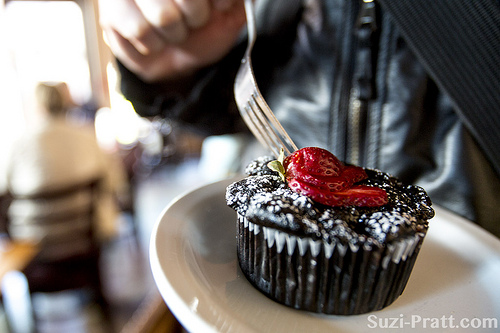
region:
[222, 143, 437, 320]
this is a cupcake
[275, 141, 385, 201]
this is a strawberry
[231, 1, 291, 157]
this is a fork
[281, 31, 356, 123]
this is a black in colour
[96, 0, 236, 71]
this is a hand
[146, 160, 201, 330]
this is the edge of a plate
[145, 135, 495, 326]
this is a white plate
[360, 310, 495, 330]
this is a word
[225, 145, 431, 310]
this is a black cupcake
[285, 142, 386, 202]
this is red in colour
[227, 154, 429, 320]
the cake is on the sauce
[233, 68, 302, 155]
the folk is metallic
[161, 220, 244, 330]
the plate is white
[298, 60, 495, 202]
the jacket is black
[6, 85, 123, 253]
the man is on the background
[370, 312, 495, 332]
the writing is suzi-pratt.com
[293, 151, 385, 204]
the red fruit is on top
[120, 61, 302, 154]
the hand is holding the folk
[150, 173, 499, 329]
A white plate beneath the cupcake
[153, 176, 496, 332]
The white plate is circular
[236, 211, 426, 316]
A wrapper on the cupcake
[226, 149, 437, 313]
A cupcake on the plate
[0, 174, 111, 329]
A chair beneath the person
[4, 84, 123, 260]
A person sitting in the chair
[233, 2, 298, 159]
A fork on top of the cupcake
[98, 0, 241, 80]
A person holding the fork with the right hand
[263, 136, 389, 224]
a red object in the cake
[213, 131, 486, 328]
a cake in the plate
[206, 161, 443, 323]
a cake in the cup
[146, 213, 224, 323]
curve of the plate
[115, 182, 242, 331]
curve of the cup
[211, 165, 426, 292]
a black cake in cup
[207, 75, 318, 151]
fork on the cake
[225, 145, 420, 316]
a tasty cake in plate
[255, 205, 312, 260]
white cream on the cake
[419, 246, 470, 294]
shadow of the cake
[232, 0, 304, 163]
silver metal fork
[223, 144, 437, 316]
circular brown cupcake on plate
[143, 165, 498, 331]
circular white plate with cupcake on it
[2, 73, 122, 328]
person wearing white shirt sitting on chair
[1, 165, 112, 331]
dark brown wooden chair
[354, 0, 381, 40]
black metal zipper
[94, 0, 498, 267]
man wearing dark brown jacket eating cupcake with fork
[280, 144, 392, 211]
thin red strawberry slices on top of cupcake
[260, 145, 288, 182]
small green strawberry stem